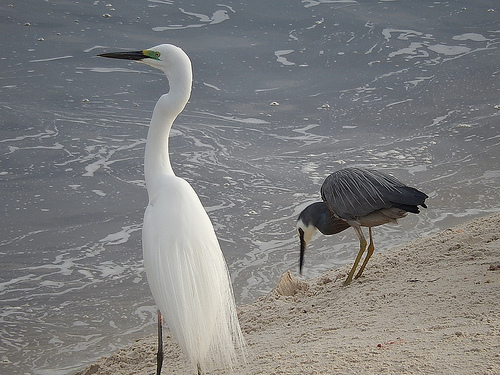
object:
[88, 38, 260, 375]
heron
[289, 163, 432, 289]
bird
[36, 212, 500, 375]
sand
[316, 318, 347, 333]
tracks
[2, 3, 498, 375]
water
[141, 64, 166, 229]
feathers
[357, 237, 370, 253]
knees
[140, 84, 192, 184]
neck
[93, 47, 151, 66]
beak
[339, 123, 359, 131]
bubbles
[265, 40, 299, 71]
bubbles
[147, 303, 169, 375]
legs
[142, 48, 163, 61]
spot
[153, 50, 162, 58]
eye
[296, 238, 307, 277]
beak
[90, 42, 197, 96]
head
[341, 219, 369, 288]
legs